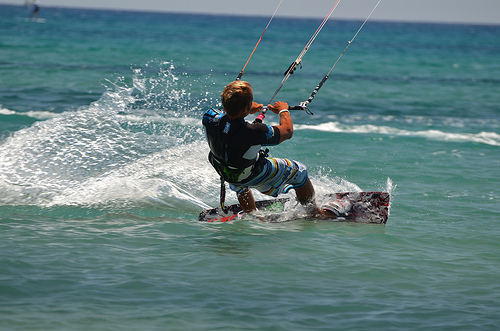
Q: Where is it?
A: This is at the ocean.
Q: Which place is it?
A: It is an ocean.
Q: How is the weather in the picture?
A: It is cloudy.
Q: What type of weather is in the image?
A: It is cloudy.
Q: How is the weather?
A: It is cloudy.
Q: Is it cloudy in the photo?
A: Yes, it is cloudy.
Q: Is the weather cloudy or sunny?
A: It is cloudy.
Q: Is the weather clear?
A: No, it is cloudy.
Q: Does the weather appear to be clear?
A: No, it is cloudy.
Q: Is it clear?
A: No, it is cloudy.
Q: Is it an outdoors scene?
A: Yes, it is outdoors.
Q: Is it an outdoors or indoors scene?
A: It is outdoors.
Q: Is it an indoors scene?
A: No, it is outdoors.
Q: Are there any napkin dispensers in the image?
A: No, there are no napkin dispensers.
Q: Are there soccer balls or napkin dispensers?
A: No, there are no napkin dispensers or soccer balls.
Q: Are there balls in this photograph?
A: No, there are no balls.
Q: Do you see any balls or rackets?
A: No, there are no balls or rackets.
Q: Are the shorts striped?
A: Yes, the shorts are striped.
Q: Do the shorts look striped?
A: Yes, the shorts are striped.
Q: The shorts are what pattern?
A: The shorts are striped.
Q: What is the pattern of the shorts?
A: The shorts are striped.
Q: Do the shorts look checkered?
A: No, the shorts are striped.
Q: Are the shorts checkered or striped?
A: The shorts are striped.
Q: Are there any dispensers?
A: No, there are no dispensers.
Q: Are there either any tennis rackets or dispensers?
A: No, there are no dispensers or tennis rackets.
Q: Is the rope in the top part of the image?
A: Yes, the rope is in the top of the image.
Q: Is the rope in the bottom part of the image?
A: No, the rope is in the top of the image.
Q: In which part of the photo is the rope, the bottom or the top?
A: The rope is in the top of the image.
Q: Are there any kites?
A: No, there are no kites.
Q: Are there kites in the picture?
A: No, there are no kites.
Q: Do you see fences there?
A: No, there are no fences.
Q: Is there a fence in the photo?
A: No, there are no fences.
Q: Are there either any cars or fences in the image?
A: No, there are no fences or cars.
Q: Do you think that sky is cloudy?
A: Yes, the sky is cloudy.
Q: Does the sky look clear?
A: No, the sky is cloudy.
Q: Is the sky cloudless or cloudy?
A: The sky is cloudy.